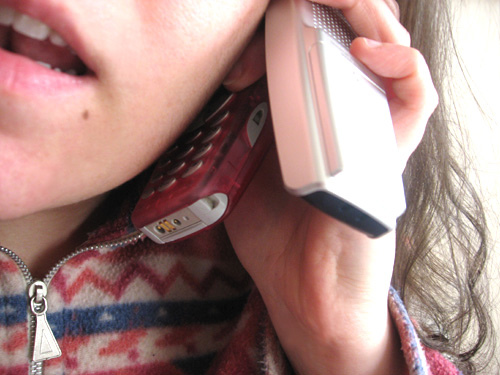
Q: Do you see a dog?
A: No, there are no dogs.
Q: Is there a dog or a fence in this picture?
A: No, there are no dogs or fences.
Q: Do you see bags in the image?
A: No, there are no bags.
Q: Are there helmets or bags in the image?
A: No, there are no bags or helmets.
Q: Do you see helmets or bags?
A: No, there are no bags or helmets.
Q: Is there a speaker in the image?
A: Yes, there is a speaker.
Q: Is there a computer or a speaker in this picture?
A: Yes, there is a speaker.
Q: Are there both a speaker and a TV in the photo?
A: No, there is a speaker but no televisions.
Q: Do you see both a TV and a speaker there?
A: No, there is a speaker but no televisions.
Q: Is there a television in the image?
A: No, there are no televisions.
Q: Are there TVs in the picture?
A: No, there are no tvs.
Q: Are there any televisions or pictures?
A: No, there are no televisions or pictures.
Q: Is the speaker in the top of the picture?
A: Yes, the speaker is in the top of the image.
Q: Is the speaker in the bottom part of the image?
A: No, the speaker is in the top of the image.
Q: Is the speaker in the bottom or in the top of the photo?
A: The speaker is in the top of the image.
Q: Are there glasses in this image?
A: No, there are no glasses.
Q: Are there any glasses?
A: No, there are no glasses.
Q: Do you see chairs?
A: No, there are no chairs.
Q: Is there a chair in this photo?
A: No, there are no chairs.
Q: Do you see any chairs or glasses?
A: No, there are no chairs or glasses.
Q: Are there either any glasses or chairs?
A: No, there are no chairs or glasses.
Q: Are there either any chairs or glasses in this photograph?
A: No, there are no chairs or glasses.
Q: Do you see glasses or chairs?
A: No, there are no chairs or glasses.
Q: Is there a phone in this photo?
A: Yes, there is a phone.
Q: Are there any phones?
A: Yes, there is a phone.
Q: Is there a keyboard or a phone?
A: Yes, there is a phone.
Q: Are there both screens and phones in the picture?
A: No, there is a phone but no screens.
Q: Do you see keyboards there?
A: No, there are no keyboards.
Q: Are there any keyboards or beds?
A: No, there are no keyboards or beds.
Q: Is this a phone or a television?
A: This is a phone.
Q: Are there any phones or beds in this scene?
A: Yes, there is a phone.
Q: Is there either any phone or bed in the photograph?
A: Yes, there is a phone.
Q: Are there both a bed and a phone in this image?
A: No, there is a phone but no beds.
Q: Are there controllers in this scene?
A: No, there are no controllers.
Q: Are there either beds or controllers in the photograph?
A: No, there are no controllers or beds.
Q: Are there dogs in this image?
A: No, there are no dogs.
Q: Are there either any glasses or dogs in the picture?
A: No, there are no dogs or glasses.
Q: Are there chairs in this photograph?
A: No, there are no chairs.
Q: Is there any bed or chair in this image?
A: No, there are no chairs or beds.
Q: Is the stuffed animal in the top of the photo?
A: Yes, the stuffed animal is in the top of the image.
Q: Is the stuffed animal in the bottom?
A: No, the stuffed animal is in the top of the image.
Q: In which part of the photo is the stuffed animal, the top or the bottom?
A: The stuffed animal is in the top of the image.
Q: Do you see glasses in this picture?
A: No, there are no glasses.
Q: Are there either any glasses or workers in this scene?
A: No, there are no glasses or workers.